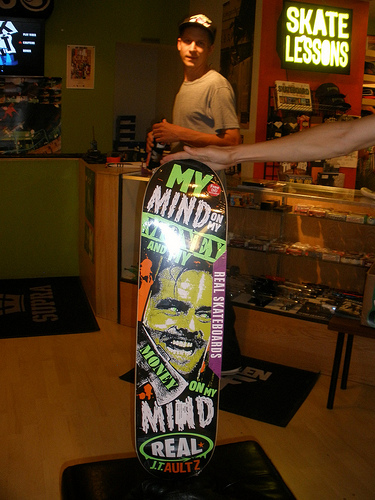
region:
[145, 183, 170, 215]
white letter on board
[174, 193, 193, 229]
white letter on board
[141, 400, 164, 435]
white letter on board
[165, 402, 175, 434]
white letter on board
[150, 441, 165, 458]
white letter on board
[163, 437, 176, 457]
white letter on board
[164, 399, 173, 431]
white letter on board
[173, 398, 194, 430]
white letter on board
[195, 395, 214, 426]
white letter on board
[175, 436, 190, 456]
white letter on board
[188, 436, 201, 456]
white letter on board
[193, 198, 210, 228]
white letter on board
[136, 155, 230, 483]
colorful skateboard deck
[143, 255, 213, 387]
image of a man on a deck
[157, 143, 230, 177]
hand on the board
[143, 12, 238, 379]
man looking at the camera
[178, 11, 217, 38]
black hat on a man's head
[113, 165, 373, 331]
glass case on a counter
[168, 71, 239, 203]
a man's grey tee shirt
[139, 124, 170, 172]
bottle in a man's hand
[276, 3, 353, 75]
neon sign on the wall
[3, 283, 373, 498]
wooden floor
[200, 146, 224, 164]
a persons hand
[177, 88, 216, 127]
man wearing a grey shirt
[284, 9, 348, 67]
a sign that is light green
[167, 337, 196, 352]
teeth on the board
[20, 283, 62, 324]
letters on the mat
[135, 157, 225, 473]
a multiple colored skate board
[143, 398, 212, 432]
the word mind in creepy white text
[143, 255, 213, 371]
an image of jack nicholson's face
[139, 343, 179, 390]
the word money in block type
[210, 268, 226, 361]
the words real skateboards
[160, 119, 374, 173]
a man's outstretched arm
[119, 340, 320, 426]
a black rug on the floor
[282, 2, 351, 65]
a neon sign that says skate lessons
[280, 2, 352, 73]
A sign that says Skate Lessons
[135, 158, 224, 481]
A skateboard with Jack Nicholson's face on it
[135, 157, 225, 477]
A skateboard with the words My Mind On My Money and My Money On My Mind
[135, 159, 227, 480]
A black, green, white, orange, and purple skateboard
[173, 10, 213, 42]
black and white hat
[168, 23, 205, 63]
face on the man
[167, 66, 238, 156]
grey colored shirt on the man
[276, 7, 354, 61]
sign that says skate lessons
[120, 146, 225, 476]
skateboard with lots of stickers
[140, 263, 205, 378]
face on the skateboard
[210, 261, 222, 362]
text that says real skateboards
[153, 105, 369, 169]
arm holding the skateboard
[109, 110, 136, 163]
black shelf in the back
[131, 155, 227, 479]
tall decorative skateboard straight up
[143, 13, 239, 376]
gorgeous man wearing a black cap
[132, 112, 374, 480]
arm holding up a skateboard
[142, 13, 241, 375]
attractive man wearing black pants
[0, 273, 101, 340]
black floor mat with crown logo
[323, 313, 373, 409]
slim wood bench with two legs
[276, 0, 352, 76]
bright neon skate lesson sign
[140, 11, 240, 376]
gorgeous man wearing a short sleeve shirt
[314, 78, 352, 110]
two stacked black caps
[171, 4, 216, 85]
the head of a man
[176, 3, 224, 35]
the hat of a man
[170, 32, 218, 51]
the eyes of a man